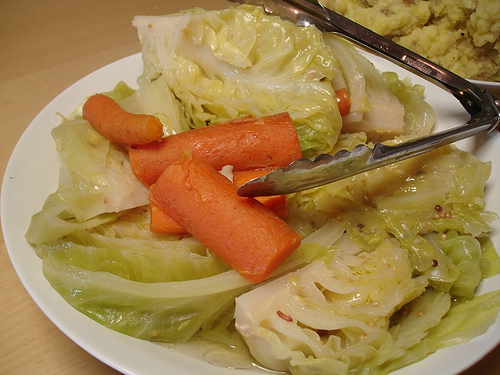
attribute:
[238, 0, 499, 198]
tong — silver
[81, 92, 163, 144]
carrot — orange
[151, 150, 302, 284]
carrot — cooked, orange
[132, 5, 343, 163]
cabbage — cooked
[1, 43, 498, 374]
plate — white, round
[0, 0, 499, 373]
table — wood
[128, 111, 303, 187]
carrot — cooked, orange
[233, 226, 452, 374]
cabbage — cooked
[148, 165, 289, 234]
carrot — cooked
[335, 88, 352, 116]
carrot — orange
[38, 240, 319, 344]
cabbage — cooked, green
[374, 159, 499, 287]
cabbage — cooked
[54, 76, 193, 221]
cabbage — cooked